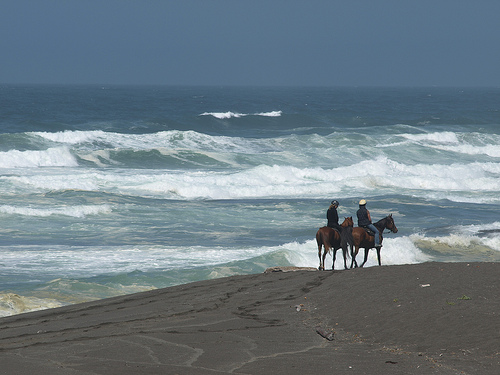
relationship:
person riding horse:
[356, 200, 381, 251] [343, 214, 397, 268]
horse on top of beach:
[343, 214, 397, 268] [1, 263, 499, 374]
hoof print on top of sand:
[284, 294, 297, 302] [1, 261, 498, 373]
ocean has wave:
[2, 84, 499, 317] [199, 110, 283, 120]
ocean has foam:
[2, 84, 499, 317] [416, 239, 499, 261]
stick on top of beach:
[421, 284, 429, 288] [1, 263, 499, 374]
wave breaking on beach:
[191, 236, 427, 269] [1, 263, 499, 374]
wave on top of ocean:
[199, 110, 283, 120] [2, 84, 499, 317]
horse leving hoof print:
[343, 214, 397, 268] [284, 294, 297, 302]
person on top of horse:
[356, 200, 381, 251] [343, 214, 397, 268]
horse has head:
[343, 214, 397, 268] [381, 214, 398, 236]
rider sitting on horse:
[328, 199, 347, 249] [316, 216, 354, 270]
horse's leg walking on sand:
[323, 242, 330, 270] [1, 261, 498, 373]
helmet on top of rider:
[331, 199, 338, 207] [328, 199, 347, 249]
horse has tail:
[343, 214, 397, 268] [340, 227, 350, 261]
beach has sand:
[1, 263, 499, 374] [1, 261, 498, 373]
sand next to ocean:
[1, 261, 498, 373] [2, 84, 499, 317]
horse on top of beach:
[316, 216, 354, 270] [1, 263, 499, 374]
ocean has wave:
[2, 84, 499, 317] [3, 130, 498, 217]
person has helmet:
[356, 200, 381, 251] [358, 199, 367, 210]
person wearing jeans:
[356, 200, 381, 251] [369, 223, 381, 245]